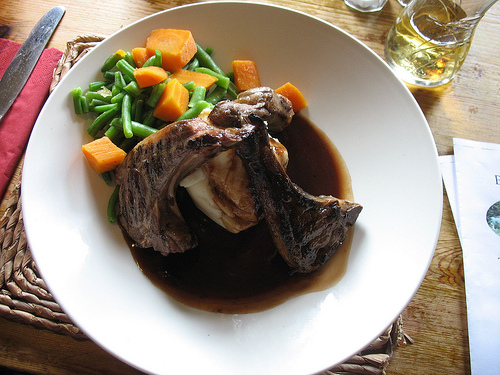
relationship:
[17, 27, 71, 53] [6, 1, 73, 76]
top of knife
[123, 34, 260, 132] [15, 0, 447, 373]
beans on plate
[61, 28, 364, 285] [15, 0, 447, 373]
food on plate